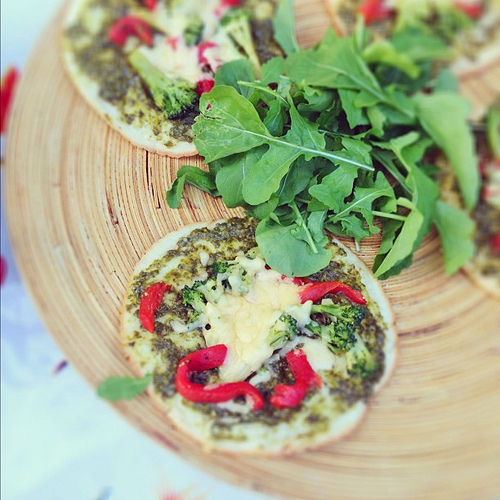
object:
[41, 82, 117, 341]
line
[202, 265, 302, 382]
cheese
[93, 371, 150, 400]
leaf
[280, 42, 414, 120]
green lettuce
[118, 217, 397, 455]
bread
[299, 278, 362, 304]
pepper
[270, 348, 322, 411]
pepper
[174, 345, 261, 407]
pepper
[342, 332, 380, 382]
broccoli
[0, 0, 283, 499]
table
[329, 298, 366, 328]
broccoli bits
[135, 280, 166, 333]
food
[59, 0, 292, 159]
pizza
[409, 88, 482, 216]
arugula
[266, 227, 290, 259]
green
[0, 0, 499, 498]
dish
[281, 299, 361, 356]
broccoli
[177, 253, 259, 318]
broccoli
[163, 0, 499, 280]
chopped lettuce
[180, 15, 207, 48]
food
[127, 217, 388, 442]
seasoning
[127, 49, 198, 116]
broccoli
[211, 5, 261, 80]
food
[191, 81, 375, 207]
leaves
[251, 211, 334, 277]
leaves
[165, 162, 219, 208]
leaves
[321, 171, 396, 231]
leaves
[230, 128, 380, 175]
stem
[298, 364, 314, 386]
red